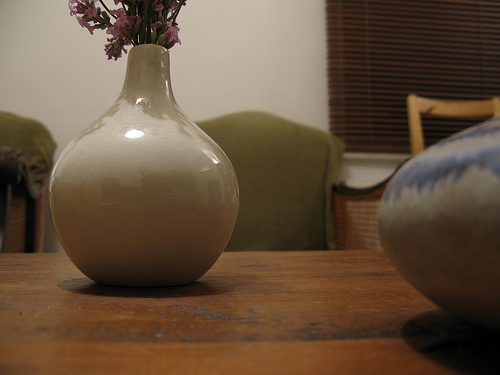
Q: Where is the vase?
A: On the table.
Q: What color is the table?
A: Brown.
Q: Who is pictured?
A: No one.